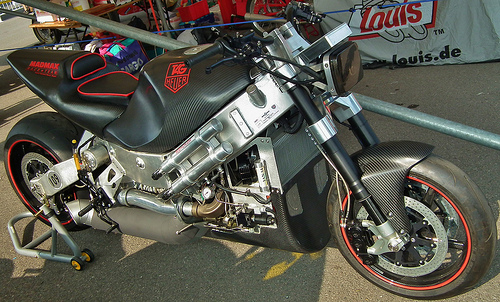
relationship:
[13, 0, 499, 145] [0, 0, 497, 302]
pole behind black motorcycle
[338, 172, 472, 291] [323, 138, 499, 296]
stripe on tire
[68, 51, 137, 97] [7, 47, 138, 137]
trim on seat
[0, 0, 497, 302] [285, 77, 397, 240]
black motorcycle has spoke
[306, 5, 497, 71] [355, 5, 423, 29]
cloth with words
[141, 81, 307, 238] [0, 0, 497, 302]
engine on black motorcycle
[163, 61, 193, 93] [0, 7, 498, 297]
red lettering on black motorcycle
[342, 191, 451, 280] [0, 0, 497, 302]
disc brake on black motorcycle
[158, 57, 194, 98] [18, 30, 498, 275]
design on motorbike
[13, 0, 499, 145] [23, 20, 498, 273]
pole running alongside bike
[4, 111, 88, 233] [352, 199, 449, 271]
tire with rim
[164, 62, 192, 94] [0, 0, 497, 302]
design on black motorcycle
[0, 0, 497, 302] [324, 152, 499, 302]
black motorcycle has tire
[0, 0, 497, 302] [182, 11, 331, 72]
black motorcycle has handles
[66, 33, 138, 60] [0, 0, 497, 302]
bags near black motorcycle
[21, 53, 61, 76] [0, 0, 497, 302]
words on black motorcycle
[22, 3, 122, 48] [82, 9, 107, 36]
table has part